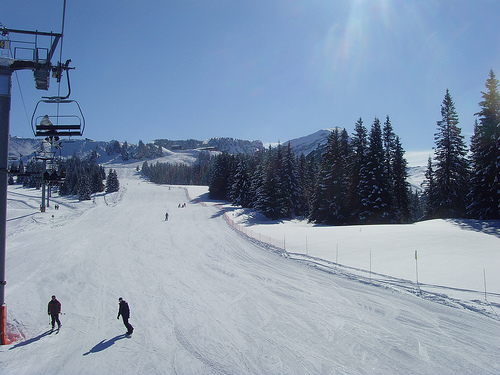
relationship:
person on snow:
[115, 297, 134, 339] [8, 182, 499, 372]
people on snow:
[44, 295, 63, 330] [8, 182, 499, 372]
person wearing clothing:
[115, 297, 134, 339] [118, 301, 132, 333]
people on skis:
[44, 295, 63, 330] [47, 323, 60, 333]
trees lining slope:
[200, 133, 428, 233] [112, 184, 440, 356]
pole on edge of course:
[479, 266, 490, 305] [11, 142, 499, 372]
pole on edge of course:
[409, 249, 429, 297] [11, 142, 499, 372]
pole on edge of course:
[363, 245, 382, 277] [11, 142, 499, 372]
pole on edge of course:
[332, 239, 344, 270] [11, 142, 499, 372]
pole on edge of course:
[301, 232, 313, 261] [11, 142, 499, 372]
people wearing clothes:
[44, 295, 63, 330] [46, 299, 63, 327]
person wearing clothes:
[114, 295, 137, 340] [117, 297, 134, 331]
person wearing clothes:
[164, 210, 170, 223] [162, 214, 171, 220]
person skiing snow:
[115, 297, 134, 339] [93, 267, 163, 299]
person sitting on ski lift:
[36, 112, 63, 146] [30, 119, 85, 144]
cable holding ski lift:
[49, 5, 67, 159] [0, 0, 97, 213]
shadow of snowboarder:
[82, 330, 125, 354] [72, 300, 182, 372]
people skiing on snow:
[46, 295, 62, 330] [8, 182, 499, 372]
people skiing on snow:
[115, 295, 132, 334] [8, 182, 499, 372]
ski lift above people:
[31, 62, 83, 137] [116, 296, 134, 337]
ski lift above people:
[36, 155, 66, 185] [47, 295, 59, 330]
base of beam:
[1, 301, 6, 347] [0, 58, 19, 338]